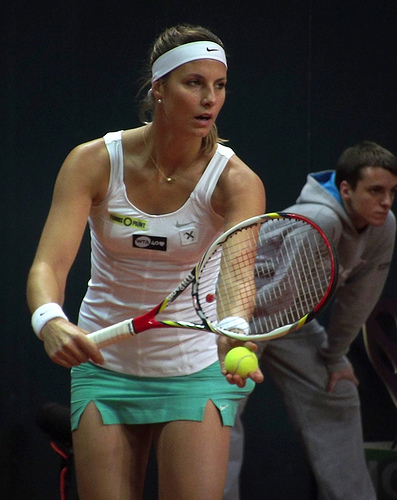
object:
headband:
[151, 40, 227, 80]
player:
[26, 23, 267, 499]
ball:
[224, 345, 258, 377]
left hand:
[215, 315, 249, 343]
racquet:
[87, 210, 335, 349]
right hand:
[36, 318, 101, 367]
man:
[223, 142, 397, 500]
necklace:
[138, 126, 172, 182]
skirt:
[70, 365, 239, 430]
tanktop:
[79, 128, 235, 376]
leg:
[70, 409, 151, 499]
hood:
[293, 168, 358, 235]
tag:
[108, 212, 148, 226]